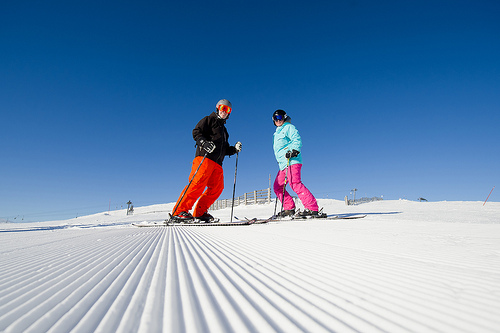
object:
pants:
[172, 156, 225, 217]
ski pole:
[279, 158, 290, 221]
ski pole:
[272, 197, 278, 220]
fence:
[208, 187, 271, 211]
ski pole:
[230, 150, 238, 222]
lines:
[135, 227, 235, 333]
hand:
[200, 140, 216, 153]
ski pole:
[169, 151, 208, 222]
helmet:
[272, 109, 288, 120]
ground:
[0, 196, 498, 333]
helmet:
[216, 99, 232, 109]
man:
[171, 99, 243, 220]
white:
[357, 231, 427, 269]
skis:
[131, 217, 257, 227]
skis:
[234, 214, 368, 222]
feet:
[193, 213, 215, 223]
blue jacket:
[272, 121, 303, 171]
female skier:
[272, 109, 320, 217]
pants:
[273, 163, 319, 212]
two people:
[171, 99, 319, 220]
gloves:
[285, 149, 300, 158]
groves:
[316, 187, 500, 237]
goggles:
[218, 104, 232, 114]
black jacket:
[192, 111, 237, 166]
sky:
[0, 0, 500, 219]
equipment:
[163, 211, 201, 223]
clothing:
[172, 111, 238, 216]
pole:
[233, 152, 239, 190]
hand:
[234, 141, 242, 152]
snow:
[0, 214, 500, 333]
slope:
[0, 201, 177, 231]